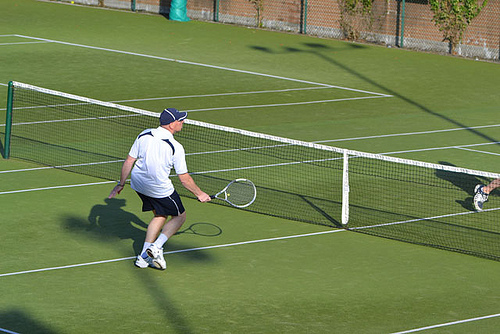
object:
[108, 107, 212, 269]
man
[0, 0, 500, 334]
court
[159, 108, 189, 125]
hat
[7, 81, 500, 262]
net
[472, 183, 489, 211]
shoe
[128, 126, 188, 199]
shirt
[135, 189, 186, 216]
shorts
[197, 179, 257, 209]
racket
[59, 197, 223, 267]
shadow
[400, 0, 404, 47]
pole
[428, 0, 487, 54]
tree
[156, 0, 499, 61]
wall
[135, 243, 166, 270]
shoes